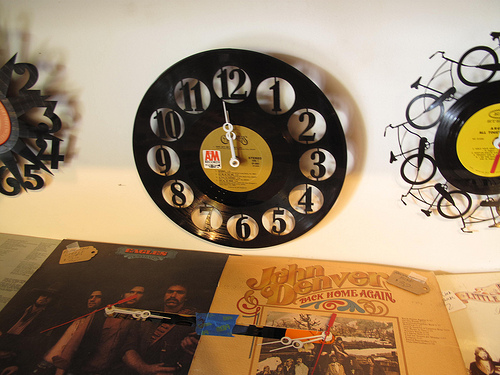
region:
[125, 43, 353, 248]
Wall clock made out of an album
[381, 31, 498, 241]
Wall deco made out of an album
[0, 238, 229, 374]
Eagles album cover on the table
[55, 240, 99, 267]
Tag taped to the eagles album cover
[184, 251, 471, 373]
John Denver album cover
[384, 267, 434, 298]
Brown tag taped to the John Denver Album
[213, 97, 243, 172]
White hour and minute hand on the clock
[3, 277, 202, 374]
Photo of the eagles on the album cover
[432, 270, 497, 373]
Partially should album cover on the right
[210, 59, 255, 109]
Number 12 on the clock face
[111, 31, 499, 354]
a clock that is inside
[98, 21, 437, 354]
a clock that is made from a vinyl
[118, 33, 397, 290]
a clock on the wall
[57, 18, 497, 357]
a black clock on the wall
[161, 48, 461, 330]
a clock with numbers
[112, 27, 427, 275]
a clock with arms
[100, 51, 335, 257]
a clock with white arms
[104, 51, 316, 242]
a black clock with arms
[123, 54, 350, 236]
a black clock with white arms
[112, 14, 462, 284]
a vinyl with arms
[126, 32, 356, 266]
A clock made from a vinyl record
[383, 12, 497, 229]
This is a clock with bicycle shapes cut out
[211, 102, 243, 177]
White hands on a clock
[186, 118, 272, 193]
This was an album by the Carpenters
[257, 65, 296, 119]
The number one cut out of vinyl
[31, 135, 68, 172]
The number four cut out of vinyl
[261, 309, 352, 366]
White hands for the minute and hour and red for seconds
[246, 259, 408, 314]
John Denver album cover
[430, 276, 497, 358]
This cover is from the Little River Band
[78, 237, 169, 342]
This album is by the Eagles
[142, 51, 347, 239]
A metal clock.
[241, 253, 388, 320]
The name John Denver.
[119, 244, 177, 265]
The word eagles.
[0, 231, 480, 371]
Several albums on the shelf.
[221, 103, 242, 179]
The clock hands on the clock.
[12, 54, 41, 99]
A metal number two.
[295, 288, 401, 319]
The words back home again.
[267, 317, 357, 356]
Clock hands on the record.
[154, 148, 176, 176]
The number 9 on the middle clock.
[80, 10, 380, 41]
The white wall in the background.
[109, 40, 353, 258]
clock with white hands hanging on a wall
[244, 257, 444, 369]
john denver back home again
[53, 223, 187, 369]
CLock with Eagles on it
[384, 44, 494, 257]
bicycle clock to the right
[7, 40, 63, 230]
sunshine clock to the left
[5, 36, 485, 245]
three clocks all in a row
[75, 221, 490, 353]
famous people clocks on the shelf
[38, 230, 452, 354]
famouse people clocks on the shelf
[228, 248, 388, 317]
John Denver Back Home Again CLock